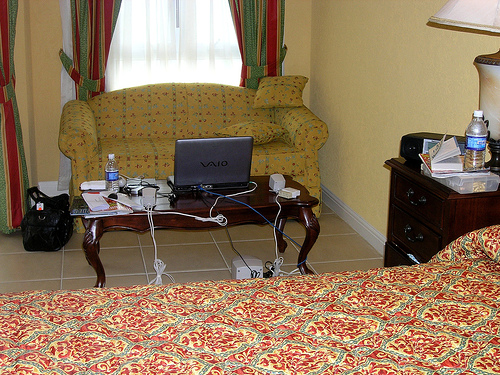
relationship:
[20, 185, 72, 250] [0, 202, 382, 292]
bag on floor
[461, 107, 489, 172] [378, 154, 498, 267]
bottle on nightstand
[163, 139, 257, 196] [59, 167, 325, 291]
laptop on top of table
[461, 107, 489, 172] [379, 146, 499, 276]
bottle on night table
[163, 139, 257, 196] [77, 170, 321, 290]
laptop on coffee table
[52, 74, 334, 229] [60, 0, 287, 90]
sofa in front of window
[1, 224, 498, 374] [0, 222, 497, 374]
spread on bed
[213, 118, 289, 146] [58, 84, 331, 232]
pillow on sofa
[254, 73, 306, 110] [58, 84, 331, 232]
pillow on sofa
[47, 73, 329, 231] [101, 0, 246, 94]
couch standing in front of window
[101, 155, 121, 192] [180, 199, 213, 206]
water on table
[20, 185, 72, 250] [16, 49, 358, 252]
bag beside sofa